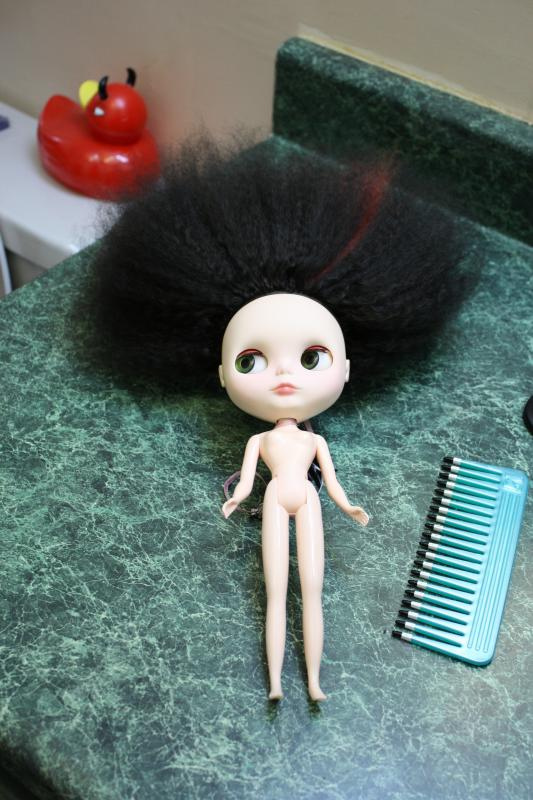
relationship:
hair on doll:
[53, 129, 494, 426] [63, 113, 503, 716]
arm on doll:
[316, 429, 370, 530] [63, 113, 503, 716]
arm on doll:
[223, 433, 257, 522] [63, 113, 503, 716]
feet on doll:
[266, 680, 291, 711] [63, 113, 503, 716]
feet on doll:
[300, 682, 331, 709] [63, 113, 503, 716]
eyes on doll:
[229, 343, 272, 380] [63, 113, 503, 716]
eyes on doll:
[295, 342, 342, 379] [63, 113, 503, 716]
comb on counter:
[394, 457, 530, 670] [2, 126, 531, 797]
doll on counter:
[63, 113, 503, 716] [2, 126, 531, 797]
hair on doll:
[65, 118, 490, 409] [63, 113, 503, 716]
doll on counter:
[85, 138, 467, 699] [0, 42, 526, 796]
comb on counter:
[394, 457, 530, 670] [2, 32, 531, 796]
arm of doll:
[223, 433, 257, 522] [85, 138, 467, 699]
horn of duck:
[121, 66, 135, 90] [38, 65, 164, 201]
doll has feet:
[63, 113, 503, 716] [307, 682, 328, 703]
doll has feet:
[63, 113, 503, 716] [268, 682, 284, 702]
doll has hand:
[63, 113, 503, 716] [346, 503, 370, 528]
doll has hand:
[63, 113, 503, 716] [218, 496, 240, 518]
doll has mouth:
[63, 113, 503, 716] [267, 380, 299, 396]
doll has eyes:
[63, 113, 503, 716] [295, 342, 342, 379]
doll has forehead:
[63, 113, 503, 716] [233, 294, 342, 338]